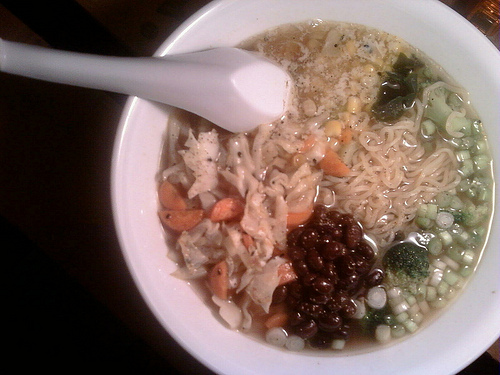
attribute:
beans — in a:
[286, 209, 371, 336]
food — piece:
[282, 189, 387, 367]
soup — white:
[157, 18, 497, 356]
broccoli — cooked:
[387, 222, 447, 295]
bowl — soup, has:
[110, 1, 498, 372]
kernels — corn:
[312, 93, 372, 158]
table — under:
[0, 1, 498, 373]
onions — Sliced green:
[439, 210, 469, 259]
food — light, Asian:
[144, 32, 496, 349]